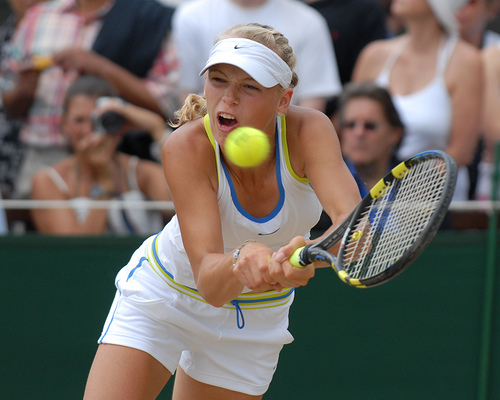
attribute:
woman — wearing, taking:
[85, 18, 409, 389]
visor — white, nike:
[204, 25, 288, 94]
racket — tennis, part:
[297, 127, 466, 313]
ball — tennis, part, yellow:
[225, 122, 277, 183]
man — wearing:
[37, 0, 187, 68]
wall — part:
[62, 240, 119, 315]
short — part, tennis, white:
[101, 309, 296, 393]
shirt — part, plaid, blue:
[244, 149, 350, 235]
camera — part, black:
[96, 100, 130, 135]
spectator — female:
[56, 66, 134, 202]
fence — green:
[323, 298, 451, 365]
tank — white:
[231, 208, 305, 255]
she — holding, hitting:
[125, 34, 327, 338]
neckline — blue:
[223, 164, 290, 228]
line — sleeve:
[191, 122, 223, 169]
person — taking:
[61, 85, 116, 169]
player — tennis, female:
[110, 22, 355, 376]